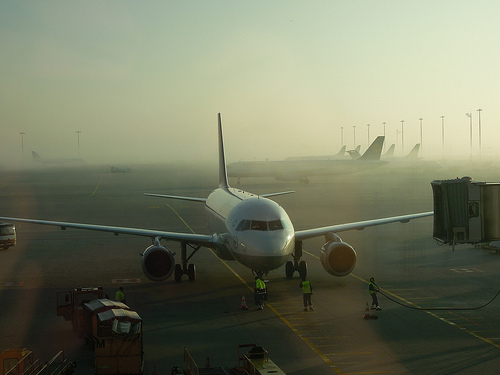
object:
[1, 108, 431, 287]
plane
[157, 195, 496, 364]
runway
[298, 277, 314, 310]
worker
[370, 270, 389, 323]
man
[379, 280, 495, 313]
hose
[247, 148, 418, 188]
planes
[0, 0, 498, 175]
background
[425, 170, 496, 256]
walkway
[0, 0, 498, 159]
sky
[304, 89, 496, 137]
lights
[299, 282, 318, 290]
vest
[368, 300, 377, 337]
cone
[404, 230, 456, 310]
ground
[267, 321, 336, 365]
line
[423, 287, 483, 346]
line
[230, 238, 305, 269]
nose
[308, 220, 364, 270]
engine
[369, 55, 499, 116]
mist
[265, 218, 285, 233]
windows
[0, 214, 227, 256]
wing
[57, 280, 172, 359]
wagon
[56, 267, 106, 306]
container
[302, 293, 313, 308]
pants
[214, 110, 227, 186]
tail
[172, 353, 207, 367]
back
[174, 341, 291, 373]
truck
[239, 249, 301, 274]
bottom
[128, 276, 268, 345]
shadow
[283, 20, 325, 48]
clouds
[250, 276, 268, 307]
person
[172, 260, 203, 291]
landing gear